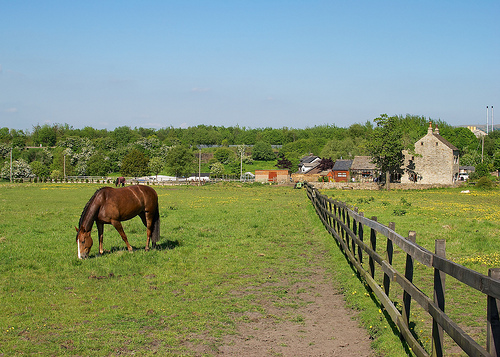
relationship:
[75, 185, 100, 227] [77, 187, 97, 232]
mane on neck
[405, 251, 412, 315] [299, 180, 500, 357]
shadow on fence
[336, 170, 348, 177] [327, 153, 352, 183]
window on a building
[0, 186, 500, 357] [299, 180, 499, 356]
ground divided by fence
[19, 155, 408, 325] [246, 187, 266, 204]
field with flowers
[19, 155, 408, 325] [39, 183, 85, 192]
field with wildflowers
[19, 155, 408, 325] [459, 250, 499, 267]
field with wildflowers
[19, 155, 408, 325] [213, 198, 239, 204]
field with wildflowers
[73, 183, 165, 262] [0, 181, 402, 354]
horse on grass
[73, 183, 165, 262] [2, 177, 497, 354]
horse on grass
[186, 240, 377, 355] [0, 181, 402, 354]
dirt on grass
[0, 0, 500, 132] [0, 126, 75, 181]
sky above trees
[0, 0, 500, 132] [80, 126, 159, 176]
sky above trees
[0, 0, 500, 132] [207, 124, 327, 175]
sky above trees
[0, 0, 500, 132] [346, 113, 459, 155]
sky above trees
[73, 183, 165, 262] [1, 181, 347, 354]
horse eating grass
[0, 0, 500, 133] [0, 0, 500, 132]
cloud in sky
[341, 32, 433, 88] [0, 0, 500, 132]
cloud in sky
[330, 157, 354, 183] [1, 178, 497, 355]
building in a field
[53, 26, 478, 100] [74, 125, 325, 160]
sky behind trees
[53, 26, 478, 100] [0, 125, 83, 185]
sky behind trees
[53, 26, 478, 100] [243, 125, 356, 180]
sky behind trees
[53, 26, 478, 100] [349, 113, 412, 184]
sky behind trees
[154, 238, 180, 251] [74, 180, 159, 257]
shadow of a horse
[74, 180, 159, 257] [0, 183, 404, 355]
horse in a field